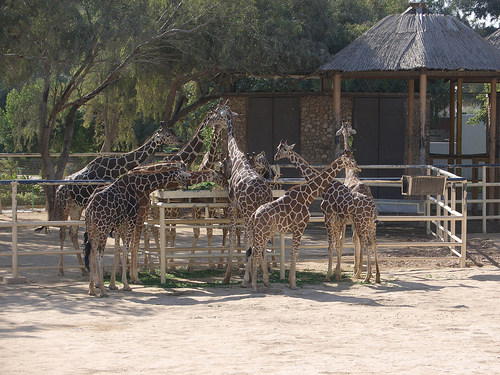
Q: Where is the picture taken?
A: The zoo.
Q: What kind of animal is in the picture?
A: Giraffe.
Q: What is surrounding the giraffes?
A: A fence.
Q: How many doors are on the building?
A: Two.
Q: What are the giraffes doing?
A: Eating.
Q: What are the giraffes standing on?
A: Dirt.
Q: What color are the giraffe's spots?
A: Brown.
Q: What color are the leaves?
A: Green.